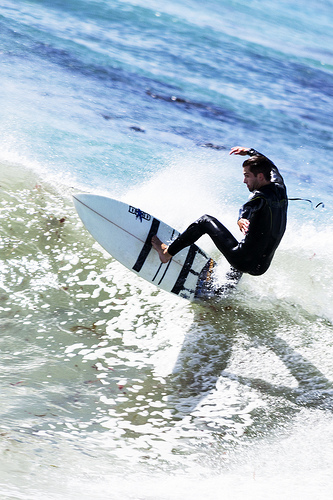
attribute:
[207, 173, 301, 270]
suit — wet, sleeved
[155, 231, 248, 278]
feet — bare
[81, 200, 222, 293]
surfboard — black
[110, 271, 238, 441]
water — white, spraying, dark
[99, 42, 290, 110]
water — blue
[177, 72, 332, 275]
man — falling, surfing, young, riding, wearing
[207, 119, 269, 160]
arms — outstretched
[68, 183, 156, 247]
board — white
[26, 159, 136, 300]
waves — white, blue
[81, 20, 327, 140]
ocean — blue, white, turqoise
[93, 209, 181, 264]
strip — black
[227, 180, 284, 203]
beard — brown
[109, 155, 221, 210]
foam — white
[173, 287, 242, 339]
cord — black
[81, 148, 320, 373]
surfer — airborn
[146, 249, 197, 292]
foot — white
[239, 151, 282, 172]
hair — brown